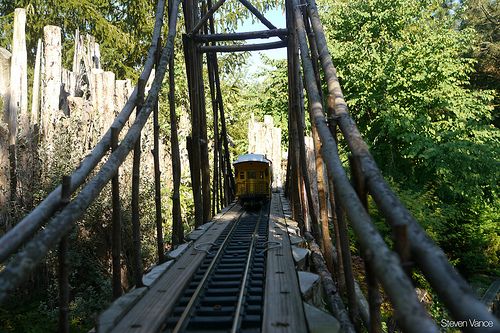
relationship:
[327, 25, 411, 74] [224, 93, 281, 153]
trees are in woods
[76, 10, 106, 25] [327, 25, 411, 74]
leaves are on trees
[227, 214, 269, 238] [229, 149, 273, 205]
tracks are for train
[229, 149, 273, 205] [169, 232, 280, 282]
train crossing bridge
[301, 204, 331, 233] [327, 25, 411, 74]
trunks are on trees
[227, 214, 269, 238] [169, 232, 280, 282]
tracks are on bridge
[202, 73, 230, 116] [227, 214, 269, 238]
ropes attached to tracks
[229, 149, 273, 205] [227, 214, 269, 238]
train on top of tracks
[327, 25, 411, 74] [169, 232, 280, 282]
trees alongside bridge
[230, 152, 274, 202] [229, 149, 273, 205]
train attached to train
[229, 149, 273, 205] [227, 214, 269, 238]
train on a tracks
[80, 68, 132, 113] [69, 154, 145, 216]
wall made of logs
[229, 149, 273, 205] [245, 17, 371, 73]
train in forest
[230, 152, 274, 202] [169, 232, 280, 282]
train on bridge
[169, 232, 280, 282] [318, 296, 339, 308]
bridge over water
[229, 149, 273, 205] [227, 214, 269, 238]
train moving on tracks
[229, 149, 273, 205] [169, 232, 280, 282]
train parked on bridge